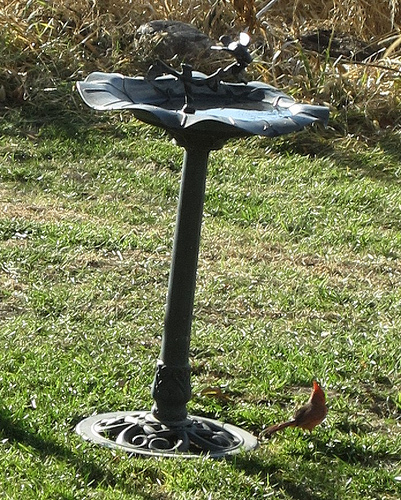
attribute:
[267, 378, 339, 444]
bird — looking, orange, standing, brown, red, sculpture, cardinal, here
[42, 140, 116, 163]
grass — dry, green, spotty, brown, yellow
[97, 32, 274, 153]
fountain — green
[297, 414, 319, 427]
wings — brown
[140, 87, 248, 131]
bird bath — metal, statue, shaped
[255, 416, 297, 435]
tail — feathers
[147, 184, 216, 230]
pole — support, black